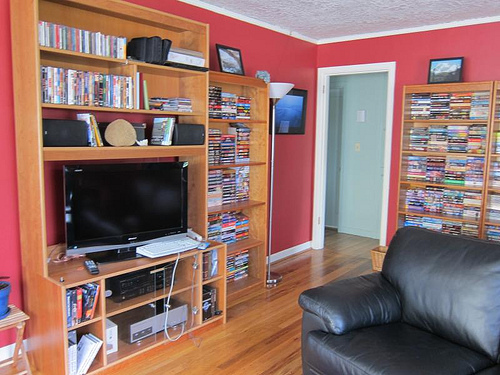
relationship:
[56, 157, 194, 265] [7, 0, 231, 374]
television on center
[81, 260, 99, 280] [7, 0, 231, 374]
control on center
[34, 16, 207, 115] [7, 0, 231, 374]
books on center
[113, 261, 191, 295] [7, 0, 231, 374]
dvr on center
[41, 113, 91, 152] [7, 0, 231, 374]
speaker on center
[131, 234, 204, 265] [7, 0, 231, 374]
keyboard on center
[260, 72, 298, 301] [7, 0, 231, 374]
lamp next to center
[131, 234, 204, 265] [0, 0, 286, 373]
keyboard on mantel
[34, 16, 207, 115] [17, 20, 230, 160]
books on shelf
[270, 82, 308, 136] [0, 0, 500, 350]
portrait on wall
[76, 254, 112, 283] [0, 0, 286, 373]
remote on mantel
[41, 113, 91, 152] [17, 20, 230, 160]
speaker on shelf